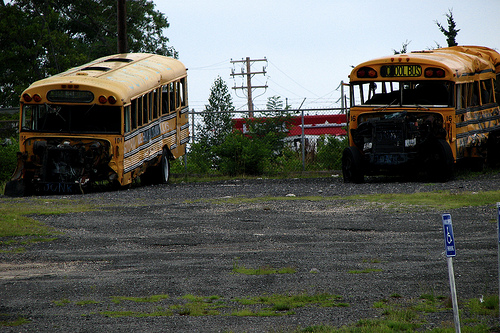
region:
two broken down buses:
[15, 31, 490, 175]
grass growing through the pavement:
[8, 183, 485, 330]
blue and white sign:
[438, 209, 453, 250]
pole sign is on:
[440, 254, 465, 323]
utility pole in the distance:
[228, 50, 278, 134]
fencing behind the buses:
[2, 101, 354, 172]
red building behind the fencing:
[223, 98, 338, 160]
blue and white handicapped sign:
[438, 208, 458, 258]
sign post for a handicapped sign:
[447, 255, 457, 329]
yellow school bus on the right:
[337, 40, 495, 183]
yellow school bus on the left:
[13, 48, 195, 201]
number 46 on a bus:
[443, 113, 455, 123]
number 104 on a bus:
[113, 135, 126, 144]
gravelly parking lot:
[1, 178, 494, 331]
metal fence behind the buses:
[161, 104, 355, 177]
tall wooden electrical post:
[229, 50, 271, 139]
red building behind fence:
[227, 108, 350, 168]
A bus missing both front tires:
[13, 49, 194, 199]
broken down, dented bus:
[12, 41, 204, 201]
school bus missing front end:
[335, 35, 494, 182]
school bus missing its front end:
[7, 51, 193, 198]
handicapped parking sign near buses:
[418, 205, 486, 332]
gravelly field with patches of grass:
[5, 190, 492, 331]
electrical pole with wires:
[209, 49, 290, 132]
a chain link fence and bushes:
[192, 106, 351, 169]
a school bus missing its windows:
[15, 50, 212, 197]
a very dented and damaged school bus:
[343, 40, 498, 180]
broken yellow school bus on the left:
[16, 50, 190, 185]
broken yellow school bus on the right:
[341, 43, 498, 186]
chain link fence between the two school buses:
[189, 104, 346, 184]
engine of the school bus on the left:
[15, 137, 113, 192]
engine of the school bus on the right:
[346, 118, 437, 178]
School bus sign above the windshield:
[379, 62, 419, 74]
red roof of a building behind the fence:
[229, 115, 349, 136]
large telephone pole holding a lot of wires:
[227, 55, 270, 115]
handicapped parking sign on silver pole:
[440, 212, 459, 331]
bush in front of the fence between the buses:
[212, 127, 279, 178]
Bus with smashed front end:
[7, 48, 189, 193]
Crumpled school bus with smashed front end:
[338, 45, 495, 186]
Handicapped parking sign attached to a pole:
[434, 208, 475, 331]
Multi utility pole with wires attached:
[223, 51, 276, 166]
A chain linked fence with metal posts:
[188, 108, 358, 177]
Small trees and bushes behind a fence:
[189, 78, 341, 185]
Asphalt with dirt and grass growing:
[20, 180, 415, 332]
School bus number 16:
[338, 42, 463, 184]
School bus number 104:
[14, 78, 128, 200]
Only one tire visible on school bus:
[14, 51, 190, 195]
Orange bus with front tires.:
[340, 42, 499, 184]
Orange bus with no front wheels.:
[12, 52, 191, 192]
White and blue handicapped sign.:
[440, 212, 455, 259]